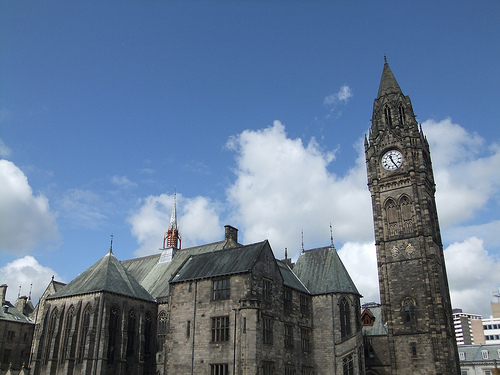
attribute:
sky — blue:
[0, 0, 499, 282]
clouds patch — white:
[235, 130, 365, 249]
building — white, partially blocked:
[450, 301, 498, 373]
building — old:
[1, 47, 465, 373]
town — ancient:
[5, 52, 492, 372]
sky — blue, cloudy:
[241, 146, 484, 298]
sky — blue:
[20, 21, 484, 306]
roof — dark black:
[167, 248, 264, 277]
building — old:
[164, 239, 366, 371]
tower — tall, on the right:
[363, 54, 460, 374]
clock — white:
[376, 143, 408, 171]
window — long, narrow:
[143, 305, 159, 373]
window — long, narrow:
[119, 305, 137, 371]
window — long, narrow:
[105, 303, 124, 373]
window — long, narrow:
[83, 302, 100, 370]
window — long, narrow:
[45, 302, 69, 368]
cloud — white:
[418, 114, 498, 319]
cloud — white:
[0, 148, 67, 254]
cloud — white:
[127, 186, 228, 261]